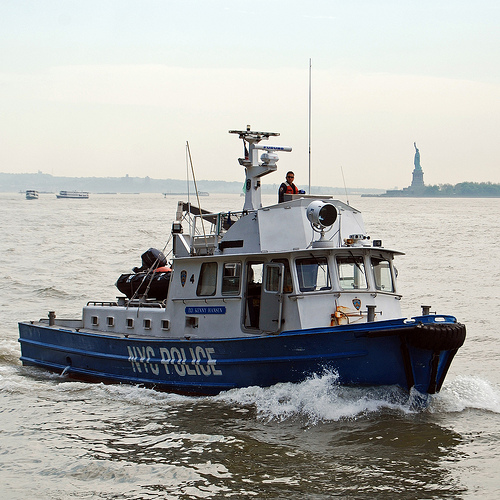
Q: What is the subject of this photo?
A: Boat.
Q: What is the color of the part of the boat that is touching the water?
A: Blue.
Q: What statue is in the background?
A: Statue of Liberty.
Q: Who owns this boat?
A: New York City Police.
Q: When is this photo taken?
A: Daytime.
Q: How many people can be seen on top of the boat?
A: One.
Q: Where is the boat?
A: Ocean.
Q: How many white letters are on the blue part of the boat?
A: Nine.